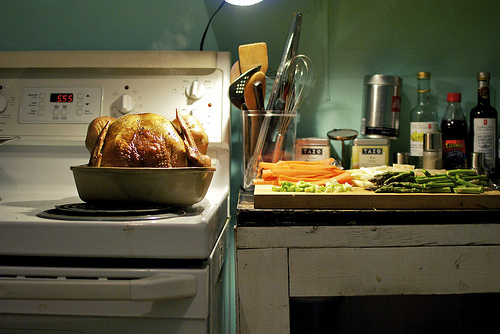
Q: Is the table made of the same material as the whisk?
A: No, the table is made of wood and the whisk is made of metal.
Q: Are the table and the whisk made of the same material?
A: No, the table is made of wood and the whisk is made of metal.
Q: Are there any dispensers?
A: No, there are no dispensers.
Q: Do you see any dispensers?
A: No, there are no dispensers.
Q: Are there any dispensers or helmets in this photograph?
A: No, there are no dispensers or helmets.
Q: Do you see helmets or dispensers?
A: No, there are no dispensers or helmets.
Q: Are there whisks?
A: Yes, there is a whisk.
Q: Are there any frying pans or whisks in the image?
A: Yes, there is a whisk.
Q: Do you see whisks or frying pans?
A: Yes, there is a whisk.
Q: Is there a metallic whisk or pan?
A: Yes, there is a metal whisk.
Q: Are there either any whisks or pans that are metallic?
A: Yes, the whisk is metallic.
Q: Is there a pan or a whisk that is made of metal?
A: Yes, the whisk is made of metal.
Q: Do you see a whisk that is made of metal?
A: Yes, there is a whisk that is made of metal.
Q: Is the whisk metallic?
A: Yes, the whisk is metallic.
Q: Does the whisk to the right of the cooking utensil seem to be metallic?
A: Yes, the whisk is metallic.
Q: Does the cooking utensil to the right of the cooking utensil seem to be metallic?
A: Yes, the whisk is metallic.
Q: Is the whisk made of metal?
A: Yes, the whisk is made of metal.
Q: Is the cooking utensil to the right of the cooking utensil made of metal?
A: Yes, the whisk is made of metal.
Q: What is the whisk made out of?
A: The whisk is made of metal.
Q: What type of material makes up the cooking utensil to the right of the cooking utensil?
A: The whisk is made of metal.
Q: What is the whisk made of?
A: The whisk is made of metal.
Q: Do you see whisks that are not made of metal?
A: No, there is a whisk but it is made of metal.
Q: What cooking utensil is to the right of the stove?
A: The cooking utensil is a whisk.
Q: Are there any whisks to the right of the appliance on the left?
A: Yes, there is a whisk to the right of the stove.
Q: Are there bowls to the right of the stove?
A: No, there is a whisk to the right of the stove.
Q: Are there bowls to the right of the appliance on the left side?
A: No, there is a whisk to the right of the stove.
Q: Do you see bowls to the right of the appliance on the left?
A: No, there is a whisk to the right of the stove.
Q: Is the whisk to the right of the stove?
A: Yes, the whisk is to the right of the stove.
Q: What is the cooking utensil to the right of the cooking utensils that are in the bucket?
A: The cooking utensil is a whisk.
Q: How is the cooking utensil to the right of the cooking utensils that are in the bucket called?
A: The cooking utensil is a whisk.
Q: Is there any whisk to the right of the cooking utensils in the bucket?
A: Yes, there is a whisk to the right of the cooking utensils.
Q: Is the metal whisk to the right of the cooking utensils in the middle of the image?
A: Yes, the whisk is to the right of the cooking utensils.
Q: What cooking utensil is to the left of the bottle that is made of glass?
A: The cooking utensil is a whisk.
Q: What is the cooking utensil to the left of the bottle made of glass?
A: The cooking utensil is a whisk.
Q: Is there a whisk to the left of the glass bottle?
A: Yes, there is a whisk to the left of the bottle.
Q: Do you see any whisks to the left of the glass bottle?
A: Yes, there is a whisk to the left of the bottle.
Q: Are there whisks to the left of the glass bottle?
A: Yes, there is a whisk to the left of the bottle.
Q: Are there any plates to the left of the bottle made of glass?
A: No, there is a whisk to the left of the bottle.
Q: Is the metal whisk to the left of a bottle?
A: Yes, the whisk is to the left of a bottle.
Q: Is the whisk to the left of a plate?
A: No, the whisk is to the left of a bottle.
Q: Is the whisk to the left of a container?
A: Yes, the whisk is to the left of a container.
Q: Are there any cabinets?
A: No, there are no cabinets.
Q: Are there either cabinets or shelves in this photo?
A: No, there are no cabinets or shelves.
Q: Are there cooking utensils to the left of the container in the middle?
A: Yes, there is a cooking utensil to the left of the container.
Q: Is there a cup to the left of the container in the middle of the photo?
A: No, there is a cooking utensil to the left of the container.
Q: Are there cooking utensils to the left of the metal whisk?
A: Yes, there is a cooking utensil to the left of the whisk.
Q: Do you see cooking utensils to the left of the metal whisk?
A: Yes, there is a cooking utensil to the left of the whisk.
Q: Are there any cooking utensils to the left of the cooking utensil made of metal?
A: Yes, there is a cooking utensil to the left of the whisk.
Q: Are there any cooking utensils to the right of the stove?
A: Yes, there is a cooking utensil to the right of the stove.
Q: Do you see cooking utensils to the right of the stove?
A: Yes, there is a cooking utensil to the right of the stove.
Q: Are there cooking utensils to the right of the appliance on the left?
A: Yes, there is a cooking utensil to the right of the stove.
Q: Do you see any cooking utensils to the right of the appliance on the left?
A: Yes, there is a cooking utensil to the right of the stove.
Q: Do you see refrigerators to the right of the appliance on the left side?
A: No, there is a cooking utensil to the right of the stove.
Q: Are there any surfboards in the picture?
A: No, there are no surfboards.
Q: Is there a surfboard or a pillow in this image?
A: No, there are no surfboards or pillows.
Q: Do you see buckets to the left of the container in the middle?
A: Yes, there is a bucket to the left of the container.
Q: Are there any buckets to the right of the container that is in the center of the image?
A: No, the bucket is to the left of the container.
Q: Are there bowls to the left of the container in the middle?
A: No, there is a bucket to the left of the container.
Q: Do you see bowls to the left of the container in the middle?
A: No, there is a bucket to the left of the container.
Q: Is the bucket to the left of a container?
A: Yes, the bucket is to the left of a container.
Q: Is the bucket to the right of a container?
A: No, the bucket is to the left of a container.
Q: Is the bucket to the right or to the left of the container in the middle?
A: The bucket is to the left of the container.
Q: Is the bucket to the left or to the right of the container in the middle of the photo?
A: The bucket is to the left of the container.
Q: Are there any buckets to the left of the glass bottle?
A: Yes, there is a bucket to the left of the bottle.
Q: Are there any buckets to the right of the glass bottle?
A: No, the bucket is to the left of the bottle.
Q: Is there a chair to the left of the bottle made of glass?
A: No, there is a bucket to the left of the bottle.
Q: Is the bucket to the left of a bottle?
A: Yes, the bucket is to the left of a bottle.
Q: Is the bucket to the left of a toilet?
A: No, the bucket is to the left of a bottle.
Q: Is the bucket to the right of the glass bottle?
A: No, the bucket is to the left of the bottle.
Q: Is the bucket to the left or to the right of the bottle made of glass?
A: The bucket is to the left of the bottle.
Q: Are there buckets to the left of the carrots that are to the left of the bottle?
A: Yes, there is a bucket to the left of the carrots.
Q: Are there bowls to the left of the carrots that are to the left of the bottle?
A: No, there is a bucket to the left of the carrots.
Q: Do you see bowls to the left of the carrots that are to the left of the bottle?
A: No, there is a bucket to the left of the carrots.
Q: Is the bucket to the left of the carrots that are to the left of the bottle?
A: Yes, the bucket is to the left of the carrots.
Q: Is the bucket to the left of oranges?
A: No, the bucket is to the left of the carrots.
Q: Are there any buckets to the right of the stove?
A: Yes, there is a bucket to the right of the stove.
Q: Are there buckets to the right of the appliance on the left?
A: Yes, there is a bucket to the right of the stove.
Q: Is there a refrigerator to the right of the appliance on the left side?
A: No, there is a bucket to the right of the stove.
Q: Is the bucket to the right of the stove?
A: Yes, the bucket is to the right of the stove.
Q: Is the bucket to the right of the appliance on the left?
A: Yes, the bucket is to the right of the stove.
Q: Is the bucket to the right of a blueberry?
A: No, the bucket is to the right of the stove.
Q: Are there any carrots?
A: Yes, there are carrots.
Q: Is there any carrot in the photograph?
A: Yes, there are carrots.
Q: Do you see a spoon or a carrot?
A: Yes, there are carrots.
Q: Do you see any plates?
A: No, there are no plates.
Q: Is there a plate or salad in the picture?
A: No, there are no plates or salad.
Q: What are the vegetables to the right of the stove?
A: The vegetables are carrots.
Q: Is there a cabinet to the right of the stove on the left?
A: No, there are carrots to the right of the stove.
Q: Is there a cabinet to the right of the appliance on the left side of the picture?
A: No, there are carrots to the right of the stove.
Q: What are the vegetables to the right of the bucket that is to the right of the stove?
A: The vegetables are carrots.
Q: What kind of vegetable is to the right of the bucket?
A: The vegetables are carrots.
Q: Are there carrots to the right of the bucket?
A: Yes, there are carrots to the right of the bucket.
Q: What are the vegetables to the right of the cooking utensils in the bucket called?
A: The vegetables are carrots.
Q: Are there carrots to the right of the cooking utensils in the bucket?
A: Yes, there are carrots to the right of the cooking utensils.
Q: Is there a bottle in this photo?
A: Yes, there is a bottle.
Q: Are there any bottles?
A: Yes, there is a bottle.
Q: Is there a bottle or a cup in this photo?
A: Yes, there is a bottle.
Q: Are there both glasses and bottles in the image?
A: No, there is a bottle but no glasses.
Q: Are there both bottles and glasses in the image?
A: No, there is a bottle but no glasses.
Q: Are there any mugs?
A: No, there are no mugs.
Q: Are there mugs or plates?
A: No, there are no mugs or plates.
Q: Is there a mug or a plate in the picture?
A: No, there are no mugs or plates.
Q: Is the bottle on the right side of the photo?
A: Yes, the bottle is on the right of the image.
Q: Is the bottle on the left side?
A: No, the bottle is on the right of the image.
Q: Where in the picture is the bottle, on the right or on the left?
A: The bottle is on the right of the image.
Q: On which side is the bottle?
A: The bottle is on the right of the image.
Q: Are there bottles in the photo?
A: Yes, there is a bottle.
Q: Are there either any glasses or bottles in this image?
A: Yes, there is a bottle.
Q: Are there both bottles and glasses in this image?
A: No, there is a bottle but no glasses.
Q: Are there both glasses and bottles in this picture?
A: No, there is a bottle but no glasses.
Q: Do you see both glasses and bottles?
A: No, there is a bottle but no glasses.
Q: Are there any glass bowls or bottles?
A: Yes, there is a glass bottle.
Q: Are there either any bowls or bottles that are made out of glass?
A: Yes, the bottle is made of glass.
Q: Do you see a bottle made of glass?
A: Yes, there is a bottle that is made of glass.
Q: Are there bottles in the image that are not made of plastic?
A: Yes, there is a bottle that is made of glass.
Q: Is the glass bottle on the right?
A: Yes, the bottle is on the right of the image.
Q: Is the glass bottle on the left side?
A: No, the bottle is on the right of the image.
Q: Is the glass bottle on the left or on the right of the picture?
A: The bottle is on the right of the image.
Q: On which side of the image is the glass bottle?
A: The bottle is on the right of the image.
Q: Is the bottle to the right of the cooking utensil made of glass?
A: Yes, the bottle is made of glass.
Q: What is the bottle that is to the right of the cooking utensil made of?
A: The bottle is made of glass.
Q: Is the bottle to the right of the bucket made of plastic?
A: No, the bottle is made of glass.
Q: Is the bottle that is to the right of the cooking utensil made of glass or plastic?
A: The bottle is made of glass.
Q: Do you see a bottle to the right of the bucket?
A: Yes, there is a bottle to the right of the bucket.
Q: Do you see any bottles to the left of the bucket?
A: No, the bottle is to the right of the bucket.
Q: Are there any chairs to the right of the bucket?
A: No, there is a bottle to the right of the bucket.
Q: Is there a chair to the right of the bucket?
A: No, there is a bottle to the right of the bucket.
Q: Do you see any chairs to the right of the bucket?
A: No, there is a bottle to the right of the bucket.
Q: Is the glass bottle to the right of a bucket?
A: Yes, the bottle is to the right of a bucket.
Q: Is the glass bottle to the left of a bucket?
A: No, the bottle is to the right of a bucket.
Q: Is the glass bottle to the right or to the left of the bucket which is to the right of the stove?
A: The bottle is to the right of the bucket.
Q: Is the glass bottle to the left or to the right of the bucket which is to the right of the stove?
A: The bottle is to the right of the bucket.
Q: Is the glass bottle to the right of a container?
A: Yes, the bottle is to the right of a container.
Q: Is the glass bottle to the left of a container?
A: No, the bottle is to the right of a container.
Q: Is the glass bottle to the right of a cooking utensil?
A: Yes, the bottle is to the right of a cooking utensil.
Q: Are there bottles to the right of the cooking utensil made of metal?
A: Yes, there is a bottle to the right of the whisk.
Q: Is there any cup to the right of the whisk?
A: No, there is a bottle to the right of the whisk.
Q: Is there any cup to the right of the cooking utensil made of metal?
A: No, there is a bottle to the right of the whisk.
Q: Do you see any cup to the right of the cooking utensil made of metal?
A: No, there is a bottle to the right of the whisk.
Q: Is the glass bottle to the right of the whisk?
A: Yes, the bottle is to the right of the whisk.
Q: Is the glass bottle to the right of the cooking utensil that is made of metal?
A: Yes, the bottle is to the right of the whisk.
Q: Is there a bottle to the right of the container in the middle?
A: Yes, there is a bottle to the right of the container.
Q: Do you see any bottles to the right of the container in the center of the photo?
A: Yes, there is a bottle to the right of the container.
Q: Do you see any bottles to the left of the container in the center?
A: No, the bottle is to the right of the container.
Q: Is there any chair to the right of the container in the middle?
A: No, there is a bottle to the right of the container.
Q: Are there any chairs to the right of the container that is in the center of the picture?
A: No, there is a bottle to the right of the container.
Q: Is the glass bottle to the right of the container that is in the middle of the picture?
A: Yes, the bottle is to the right of the container.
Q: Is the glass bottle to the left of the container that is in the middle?
A: No, the bottle is to the right of the container.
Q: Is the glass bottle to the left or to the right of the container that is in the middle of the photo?
A: The bottle is to the right of the container.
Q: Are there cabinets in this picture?
A: No, there are no cabinets.